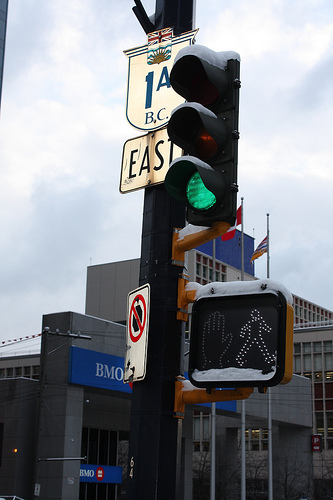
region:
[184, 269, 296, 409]
walking sign on a pole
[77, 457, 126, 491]
sign for a bank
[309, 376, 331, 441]
windows on a building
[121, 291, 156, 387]
no walking sign on a pole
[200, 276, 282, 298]
snow on a pedestrian walking sign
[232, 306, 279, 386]
lighted image of a pedestrian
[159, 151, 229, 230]
green traffic light on a signal sign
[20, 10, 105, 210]
cloudy sky in the distance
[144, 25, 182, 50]
british flag on a sign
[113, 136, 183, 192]
direction sign on a pole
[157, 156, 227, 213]
green signal is on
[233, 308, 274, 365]
man walking signal is lit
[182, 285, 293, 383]
guiding traffic light on pole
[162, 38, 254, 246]
traffic signal on pole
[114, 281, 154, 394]
sign attached to pole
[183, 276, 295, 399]
snow on traffic signal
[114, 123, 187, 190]
direction sign on pole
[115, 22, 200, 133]
street sign on pole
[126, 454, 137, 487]
number 64 on pole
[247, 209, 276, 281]
flag on top of building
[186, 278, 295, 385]
street crossing sign covered in snow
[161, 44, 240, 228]
traffic signal wiht lowest light shining green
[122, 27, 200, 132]
Bristish Columbia roadway sign indicating 1A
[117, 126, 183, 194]
white rectangular direction sign reading EAST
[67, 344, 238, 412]
long blue business sign displaying letters BMO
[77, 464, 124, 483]
small blue business sign displaying letters BMO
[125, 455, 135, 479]
white number 64 on black traffic signal pole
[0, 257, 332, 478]
large multi-story building constructed of concrete, metal and glass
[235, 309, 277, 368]
outline of a walking person on traffic signal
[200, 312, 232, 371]
outline of a hand on a traffic signal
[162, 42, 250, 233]
a big street light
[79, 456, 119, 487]
the logo of a company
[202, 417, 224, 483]
a skinny grey pole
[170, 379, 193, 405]
a street light pole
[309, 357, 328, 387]
a very small window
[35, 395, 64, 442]
a big grey wall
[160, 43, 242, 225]
Traffic light with green lit up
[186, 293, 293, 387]
Crossing sign with walking figure lit up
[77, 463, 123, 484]
Blue sign with BMO in white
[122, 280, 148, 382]
White no stop sign sign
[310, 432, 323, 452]
Red sign with a white P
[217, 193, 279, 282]
Two flages on silver poles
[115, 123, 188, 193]
White sign with EAST in black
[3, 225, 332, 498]
Large brick building with blue accents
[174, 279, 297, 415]
Crossing sign with snow on it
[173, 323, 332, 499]
Building with lights visible through windows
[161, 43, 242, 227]
Streetlight showing a green light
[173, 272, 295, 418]
Crosswalk sign showing a walk signal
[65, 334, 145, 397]
a blue and white sign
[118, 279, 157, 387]
a white and black sign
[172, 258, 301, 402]
a black cross walk sign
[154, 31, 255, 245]
a black traffic light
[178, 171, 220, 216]
traffic light lit green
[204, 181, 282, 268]
flags on a pole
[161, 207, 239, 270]
yellow arm of traffic light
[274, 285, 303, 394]
yellow trim on cross sign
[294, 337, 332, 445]
multiple windows on building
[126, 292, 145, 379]
white black and red sign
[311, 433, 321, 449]
red parking sign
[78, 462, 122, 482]
blue sign on the building